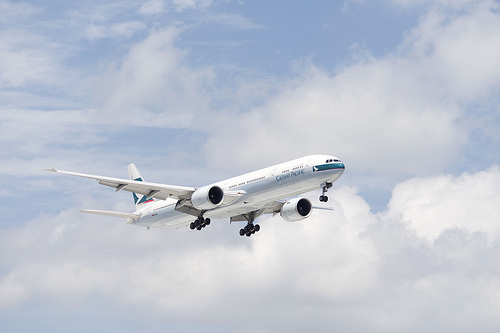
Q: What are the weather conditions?
A: It is cloudy.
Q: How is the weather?
A: It is cloudy.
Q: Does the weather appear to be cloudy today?
A: Yes, it is cloudy.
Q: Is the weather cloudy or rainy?
A: It is cloudy.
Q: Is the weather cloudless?
A: No, it is cloudy.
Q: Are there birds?
A: No, there are no birds.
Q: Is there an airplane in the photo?
A: Yes, there is an airplane.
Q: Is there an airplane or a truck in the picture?
A: Yes, there is an airplane.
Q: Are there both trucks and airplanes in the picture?
A: No, there is an airplane but no trucks.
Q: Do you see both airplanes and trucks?
A: No, there is an airplane but no trucks.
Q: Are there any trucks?
A: No, there are no trucks.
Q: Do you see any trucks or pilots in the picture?
A: No, there are no trucks or pilots.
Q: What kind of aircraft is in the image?
A: The aircraft is an airplane.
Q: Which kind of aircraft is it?
A: The aircraft is an airplane.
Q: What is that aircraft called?
A: This is an airplane.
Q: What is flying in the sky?
A: The plane is flying in the sky.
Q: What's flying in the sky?
A: The plane is flying in the sky.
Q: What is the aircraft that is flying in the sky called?
A: The aircraft is an airplane.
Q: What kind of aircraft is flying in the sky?
A: The aircraft is an airplane.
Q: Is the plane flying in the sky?
A: Yes, the plane is flying in the sky.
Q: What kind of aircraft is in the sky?
A: The aircraft is an airplane.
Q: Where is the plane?
A: The plane is in the sky.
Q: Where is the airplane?
A: The plane is in the sky.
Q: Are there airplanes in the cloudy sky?
A: Yes, there is an airplane in the sky.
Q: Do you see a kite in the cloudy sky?
A: No, there is an airplane in the sky.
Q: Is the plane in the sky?
A: Yes, the plane is in the sky.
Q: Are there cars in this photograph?
A: No, there are no cars.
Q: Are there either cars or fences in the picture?
A: No, there are no cars or fences.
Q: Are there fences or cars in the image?
A: No, there are no cars or fences.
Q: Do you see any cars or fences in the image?
A: No, there are no cars or fences.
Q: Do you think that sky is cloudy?
A: Yes, the sky is cloudy.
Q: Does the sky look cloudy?
A: Yes, the sky is cloudy.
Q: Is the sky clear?
A: No, the sky is cloudy.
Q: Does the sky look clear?
A: No, the sky is cloudy.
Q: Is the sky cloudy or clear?
A: The sky is cloudy.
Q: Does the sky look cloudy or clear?
A: The sky is cloudy.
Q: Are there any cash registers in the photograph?
A: No, there are no cash registers.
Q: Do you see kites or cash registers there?
A: No, there are no cash registers or kites.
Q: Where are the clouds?
A: The clouds are in the sky.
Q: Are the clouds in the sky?
A: Yes, the clouds are in the sky.